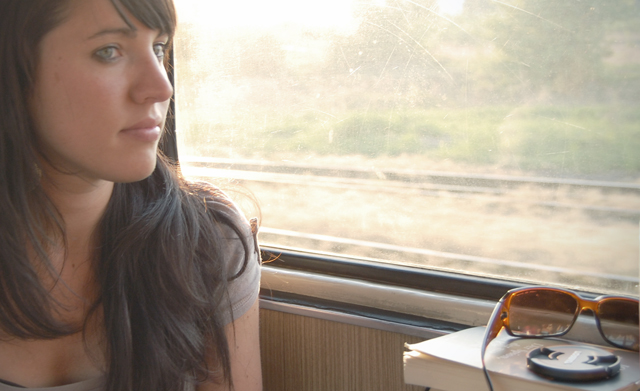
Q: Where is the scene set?
A: In a train.